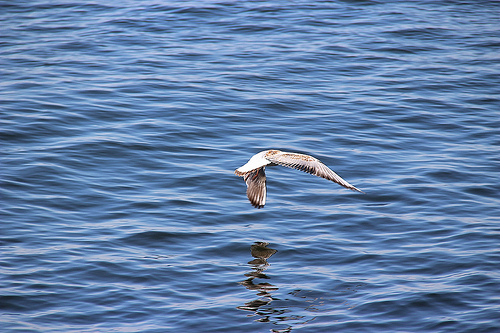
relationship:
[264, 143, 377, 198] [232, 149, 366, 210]
wing spread on bird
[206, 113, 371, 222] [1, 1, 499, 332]
bird flying over water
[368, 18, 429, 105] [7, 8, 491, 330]
ripples are in water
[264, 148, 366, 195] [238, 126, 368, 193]
wing of bird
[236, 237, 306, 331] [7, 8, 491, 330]
reflection in water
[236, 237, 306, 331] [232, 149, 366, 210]
reflection of bird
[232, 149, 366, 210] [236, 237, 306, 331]
bird in reflection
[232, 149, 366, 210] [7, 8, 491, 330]
bird in water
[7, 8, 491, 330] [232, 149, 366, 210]
water around bird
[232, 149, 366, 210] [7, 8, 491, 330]
bird low to water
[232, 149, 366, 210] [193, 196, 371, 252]
bird flying over water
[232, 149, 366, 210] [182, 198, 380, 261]
bird soaring over water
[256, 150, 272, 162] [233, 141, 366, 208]
back of a bird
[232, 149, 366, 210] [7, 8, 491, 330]
bird flying above water